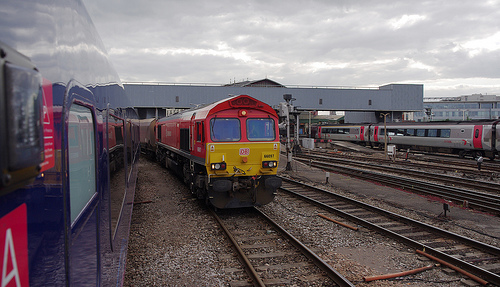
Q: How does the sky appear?
A: Very cloudy.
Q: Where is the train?
A: On train tracks.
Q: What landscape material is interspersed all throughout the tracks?
A: Rocks.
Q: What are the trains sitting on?
A: Tracks.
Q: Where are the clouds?
A: In the sky.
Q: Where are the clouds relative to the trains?
A: Above the trains.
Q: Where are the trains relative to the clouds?
A: Below the clouds.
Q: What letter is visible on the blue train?
A: A.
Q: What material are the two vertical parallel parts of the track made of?
A: Metal.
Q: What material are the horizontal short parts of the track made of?
A: Wood.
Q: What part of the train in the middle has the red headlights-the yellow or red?
A: Yellow.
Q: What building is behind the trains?
A: The station.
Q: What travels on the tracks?
A: Trains.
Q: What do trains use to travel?
A: Tracks.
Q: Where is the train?
A: In the station.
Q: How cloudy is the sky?
A: Very cloudy.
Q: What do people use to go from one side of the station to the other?
A: The overpass.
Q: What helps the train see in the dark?
A: Headlights.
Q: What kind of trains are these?
A: Passenger trains.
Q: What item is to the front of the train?
A: Train tracks.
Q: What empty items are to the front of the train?
A: Tracks.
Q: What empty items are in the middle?
A: Train tracks.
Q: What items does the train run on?
A: Tracks.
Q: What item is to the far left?
A: A train.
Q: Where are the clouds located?
A: The sky.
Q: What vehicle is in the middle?
A: A train.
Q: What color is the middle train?
A: Red and yellow.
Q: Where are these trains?
A: At the station.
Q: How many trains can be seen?
A: Three.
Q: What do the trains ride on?
A: Tracks.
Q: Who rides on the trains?
A: People.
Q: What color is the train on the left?
A: Blue.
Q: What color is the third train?
A: Silver with red doors.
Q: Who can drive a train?
A: A conductor.